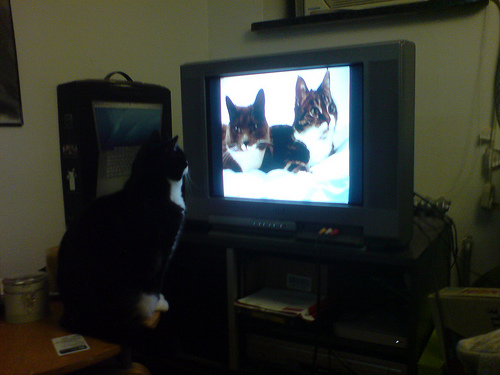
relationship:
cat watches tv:
[50, 122, 192, 350] [178, 39, 416, 258]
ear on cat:
[164, 135, 179, 153] [50, 122, 192, 350]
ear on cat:
[164, 135, 179, 153] [54, 127, 191, 372]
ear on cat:
[254, 87, 266, 108] [218, 87, 275, 173]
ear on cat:
[164, 131, 179, 153] [50, 122, 192, 350]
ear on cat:
[223, 95, 236, 119] [215, 85, 277, 173]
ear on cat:
[293, 74, 306, 96] [260, 68, 340, 180]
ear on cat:
[316, 67, 331, 89] [260, 68, 340, 180]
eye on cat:
[231, 125, 241, 133] [222, 87, 271, 173]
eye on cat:
[231, 125, 241, 133] [221, 84, 276, 172]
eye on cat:
[249, 121, 258, 131] [221, 84, 276, 172]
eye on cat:
[308, 105, 323, 118] [266, 69, 340, 174]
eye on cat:
[326, 102, 338, 114] [266, 69, 340, 174]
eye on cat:
[231, 125, 241, 133] [223, 83, 299, 189]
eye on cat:
[249, 121, 258, 131] [223, 83, 299, 189]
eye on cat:
[308, 105, 323, 118] [300, 63, 366, 170]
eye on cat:
[327, 100, 336, 115] [300, 63, 366, 170]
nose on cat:
[240, 131, 250, 145] [221, 84, 276, 172]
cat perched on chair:
[37, 129, 190, 374] [35, 234, 230, 371]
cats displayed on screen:
[215, 66, 341, 181] [204, 55, 363, 211]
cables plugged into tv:
[314, 225, 337, 246] [176, 32, 419, 245]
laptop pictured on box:
[92, 100, 167, 200] [59, 80, 175, 225]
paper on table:
[50, 331, 92, 356] [10, 264, 186, 371]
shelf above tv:
[250, 1, 490, 36] [178, 38, 415, 233]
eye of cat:
[326, 102, 338, 114] [284, 67, 342, 168]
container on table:
[2, 270, 56, 328] [30, 218, 472, 372]